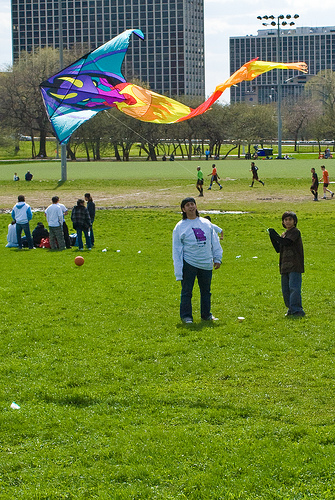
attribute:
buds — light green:
[222, 106, 275, 142]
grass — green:
[29, 238, 333, 493]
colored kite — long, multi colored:
[22, 22, 317, 148]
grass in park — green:
[39, 260, 227, 339]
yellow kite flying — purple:
[102, 45, 324, 144]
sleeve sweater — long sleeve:
[263, 224, 318, 277]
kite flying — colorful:
[31, 21, 334, 183]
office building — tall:
[230, 27, 335, 149]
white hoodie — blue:
[170, 214, 233, 281]